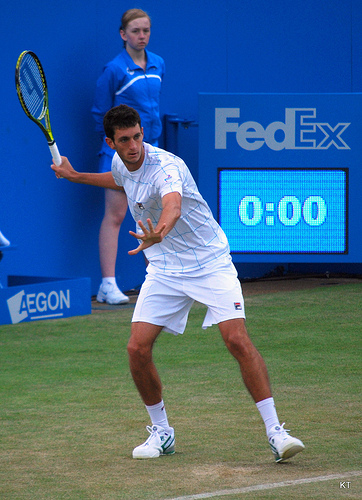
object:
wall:
[0, 0, 362, 297]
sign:
[196, 93, 362, 263]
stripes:
[161, 434, 175, 455]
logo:
[234, 301, 243, 310]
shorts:
[131, 254, 246, 336]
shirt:
[111, 141, 230, 273]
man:
[50, 103, 306, 464]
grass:
[255, 275, 357, 420]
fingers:
[128, 242, 144, 255]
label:
[161, 406, 165, 410]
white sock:
[145, 400, 171, 434]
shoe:
[132, 425, 175, 459]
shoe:
[267, 422, 303, 462]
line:
[169, 470, 362, 499]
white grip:
[48, 143, 64, 179]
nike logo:
[100, 289, 107, 296]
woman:
[92, 9, 165, 305]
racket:
[14, 50, 64, 179]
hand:
[51, 156, 70, 180]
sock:
[255, 397, 280, 436]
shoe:
[96, 282, 129, 305]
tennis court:
[0, 0, 362, 499]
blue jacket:
[90, 48, 165, 158]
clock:
[218, 168, 347, 253]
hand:
[128, 218, 166, 255]